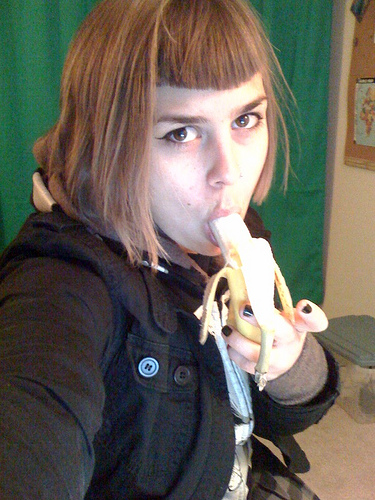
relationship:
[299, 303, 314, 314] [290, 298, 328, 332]
nail polish on pointer finger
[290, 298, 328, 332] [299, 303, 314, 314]
pointer finger has nail polish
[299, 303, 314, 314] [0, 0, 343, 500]
nail polish on girl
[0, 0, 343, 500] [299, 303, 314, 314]
girl has nail polish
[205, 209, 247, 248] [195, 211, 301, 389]
mouth around a banana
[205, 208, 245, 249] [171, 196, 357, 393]
mouth wrapped around banana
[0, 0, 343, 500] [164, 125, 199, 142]
girl has eye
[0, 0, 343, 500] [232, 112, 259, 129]
girl has eye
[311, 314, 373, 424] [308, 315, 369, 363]
bin with lid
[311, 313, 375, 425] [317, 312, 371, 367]
bin with lid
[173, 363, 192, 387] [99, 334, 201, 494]
button on pocket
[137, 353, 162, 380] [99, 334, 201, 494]
button on pocket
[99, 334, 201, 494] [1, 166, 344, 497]
pocket on shirt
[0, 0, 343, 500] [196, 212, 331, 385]
girl eats banana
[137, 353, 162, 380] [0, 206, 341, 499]
button on front of coat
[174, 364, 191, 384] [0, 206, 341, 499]
button on front of coat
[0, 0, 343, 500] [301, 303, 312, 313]
girl wears nail polish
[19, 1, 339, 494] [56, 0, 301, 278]
girl has girl hair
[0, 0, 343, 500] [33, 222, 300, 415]
girl wearing jacket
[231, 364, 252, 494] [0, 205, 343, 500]
shirt underneath coat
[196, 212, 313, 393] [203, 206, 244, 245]
banana inside mouth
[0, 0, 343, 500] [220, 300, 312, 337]
girl has fingernails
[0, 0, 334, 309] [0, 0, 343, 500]
curtain behind girl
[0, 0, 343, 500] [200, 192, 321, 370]
girl eating banana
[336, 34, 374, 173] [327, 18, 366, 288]
corkboard hanging on wall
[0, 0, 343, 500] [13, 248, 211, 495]
girl wearing coat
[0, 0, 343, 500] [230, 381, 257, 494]
girl wearing shirt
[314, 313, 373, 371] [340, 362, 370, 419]
lid on top of container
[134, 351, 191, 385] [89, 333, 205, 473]
button on pocket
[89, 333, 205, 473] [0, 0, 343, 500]
pocket on girl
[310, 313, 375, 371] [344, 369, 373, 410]
lid on container